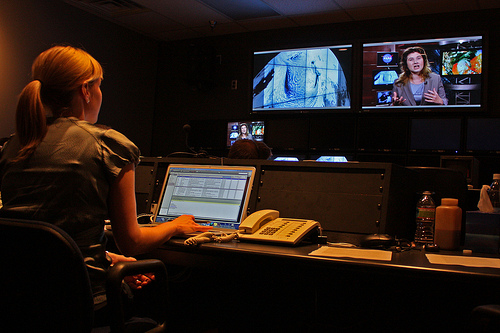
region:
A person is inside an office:
[22, 20, 473, 300]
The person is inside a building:
[16, 32, 479, 297]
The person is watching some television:
[21, 35, 497, 298]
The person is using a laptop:
[15, 25, 475, 315]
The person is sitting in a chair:
[22, 38, 480, 299]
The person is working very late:
[5, 25, 491, 310]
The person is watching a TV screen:
[2, 22, 487, 312]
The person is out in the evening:
[6, 32, 477, 288]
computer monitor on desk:
[167, 143, 255, 253]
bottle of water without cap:
[403, 178, 441, 243]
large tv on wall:
[356, 17, 491, 132]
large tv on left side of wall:
[229, 16, 369, 128]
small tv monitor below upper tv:
[216, 109, 278, 147]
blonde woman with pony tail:
[16, 39, 111, 133]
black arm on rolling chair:
[96, 239, 171, 295]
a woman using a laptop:
[11, 45, 251, 307]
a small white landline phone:
[210, 203, 305, 265]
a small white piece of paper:
[318, 233, 383, 274]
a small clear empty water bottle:
[395, 189, 440, 246]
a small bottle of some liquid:
[432, 188, 464, 248]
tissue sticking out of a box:
[455, 183, 497, 228]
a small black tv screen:
[218, 46, 362, 110]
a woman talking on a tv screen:
[354, 23, 478, 131]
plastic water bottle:
[408, 181, 433, 253]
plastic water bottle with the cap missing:
[408, 178, 439, 240]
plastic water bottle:
[485, 171, 499, 191]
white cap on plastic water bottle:
[491, 168, 499, 196]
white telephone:
[246, 198, 308, 246]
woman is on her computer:
[25, 47, 254, 255]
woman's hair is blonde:
[16, 45, 99, 154]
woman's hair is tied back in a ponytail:
[6, 45, 125, 149]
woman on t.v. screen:
[371, 42, 466, 109]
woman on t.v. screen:
[225, 110, 269, 150]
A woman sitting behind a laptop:
[12, 35, 220, 310]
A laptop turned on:
[142, 160, 251, 245]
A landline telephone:
[181, 197, 325, 250]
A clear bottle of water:
[415, 187, 435, 248]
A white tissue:
[475, 182, 495, 213]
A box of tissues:
[465, 183, 490, 250]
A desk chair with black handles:
[4, 212, 171, 329]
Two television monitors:
[244, 32, 497, 119]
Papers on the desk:
[306, 239, 497, 271]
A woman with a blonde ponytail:
[11, 43, 106, 160]